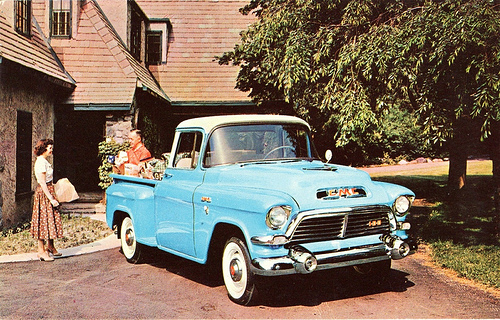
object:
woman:
[31, 138, 65, 262]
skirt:
[31, 182, 64, 239]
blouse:
[34, 155, 53, 184]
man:
[112, 128, 152, 179]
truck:
[107, 114, 417, 307]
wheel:
[350, 260, 379, 275]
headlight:
[394, 196, 411, 214]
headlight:
[268, 206, 288, 229]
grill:
[251, 204, 400, 247]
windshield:
[201, 123, 322, 165]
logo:
[327, 187, 361, 197]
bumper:
[247, 231, 409, 276]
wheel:
[221, 236, 258, 307]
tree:
[211, 1, 500, 188]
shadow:
[370, 174, 500, 248]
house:
[1, 0, 262, 232]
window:
[147, 34, 162, 62]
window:
[132, 11, 139, 53]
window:
[52, 0, 71, 37]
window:
[12, 0, 29, 36]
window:
[172, 131, 205, 170]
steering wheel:
[264, 145, 298, 159]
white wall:
[119, 215, 148, 263]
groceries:
[113, 150, 128, 166]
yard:
[0, 0, 498, 317]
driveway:
[0, 244, 499, 319]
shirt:
[112, 143, 152, 175]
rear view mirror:
[324, 149, 332, 163]